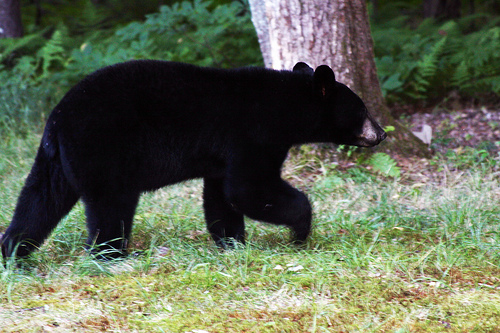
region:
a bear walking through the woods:
[17, 19, 461, 301]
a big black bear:
[26, 39, 394, 268]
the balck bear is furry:
[5, 42, 402, 279]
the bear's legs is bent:
[181, 161, 339, 260]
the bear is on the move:
[9, 84, 361, 261]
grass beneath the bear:
[20, 178, 460, 331]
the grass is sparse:
[43, 249, 459, 321]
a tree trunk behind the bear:
[247, 5, 420, 168]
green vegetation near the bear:
[10, 7, 250, 75]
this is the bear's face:
[272, 62, 389, 156]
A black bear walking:
[0, 60, 386, 262]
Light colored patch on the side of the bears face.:
[360, 117, 378, 143]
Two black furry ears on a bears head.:
[292, 62, 334, 81]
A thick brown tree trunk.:
[248, 2, 433, 156]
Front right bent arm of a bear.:
[227, 142, 314, 245]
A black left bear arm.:
[201, 170, 248, 252]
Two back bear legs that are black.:
[1, 122, 139, 263]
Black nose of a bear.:
[378, 129, 389, 142]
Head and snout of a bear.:
[313, 72, 387, 148]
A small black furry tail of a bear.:
[43, 117, 59, 157]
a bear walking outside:
[19, 45, 390, 318]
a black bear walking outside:
[43, 28, 467, 326]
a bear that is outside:
[8, 15, 460, 326]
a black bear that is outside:
[3, 25, 430, 330]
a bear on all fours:
[64, 41, 479, 327]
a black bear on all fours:
[47, 30, 417, 323]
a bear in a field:
[33, 31, 403, 332]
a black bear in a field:
[62, 33, 418, 308]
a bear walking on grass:
[61, 6, 499, 250]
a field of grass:
[214, 163, 470, 328]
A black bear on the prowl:
[25, 65, 387, 250]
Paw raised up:
[295, 202, 309, 236]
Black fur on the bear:
[149, 112, 241, 157]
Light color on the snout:
[365, 124, 372, 139]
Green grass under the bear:
[376, 211, 424, 226]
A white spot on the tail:
[45, 142, 49, 146]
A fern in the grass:
[373, 156, 391, 169]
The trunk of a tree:
[282, 8, 354, 56]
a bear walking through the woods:
[3, 55, 383, 255]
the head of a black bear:
[292, 55, 382, 145]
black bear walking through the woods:
[1, 60, 386, 263]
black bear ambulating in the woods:
[0, 60, 383, 265]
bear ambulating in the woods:
[0, 60, 380, 255]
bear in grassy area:
[2, 56, 387, 266]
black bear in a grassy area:
[3, 55, 385, 266]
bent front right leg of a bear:
[223, 158, 315, 243]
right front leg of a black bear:
[225, 158, 311, 246]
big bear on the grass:
[40, 48, 391, 280]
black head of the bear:
[301, 50, 381, 157]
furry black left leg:
[205, 179, 245, 249]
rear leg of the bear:
[15, 140, 129, 254]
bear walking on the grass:
[43, 49, 359, 257]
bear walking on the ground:
[189, 55, 351, 234]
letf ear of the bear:
[292, 58, 304, 73]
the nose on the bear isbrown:
[357, 113, 386, 150]